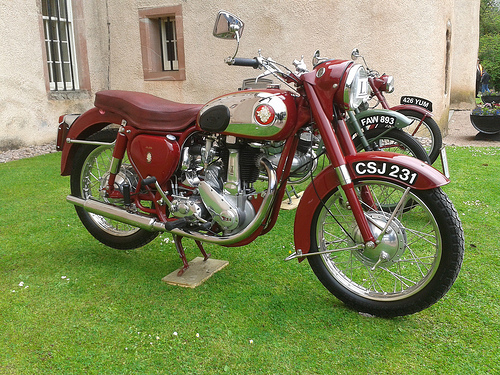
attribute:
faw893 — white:
[358, 103, 426, 154]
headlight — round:
[341, 65, 375, 112]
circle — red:
[248, 106, 315, 140]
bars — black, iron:
[155, 16, 173, 67]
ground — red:
[416, 117, 438, 141]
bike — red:
[63, 42, 465, 316]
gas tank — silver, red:
[194, 88, 309, 141]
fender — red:
[292, 133, 476, 285]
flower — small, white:
[170, 327, 187, 340]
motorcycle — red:
[45, 46, 495, 350]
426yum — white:
[400, 96, 430, 110]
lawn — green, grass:
[8, 240, 478, 370]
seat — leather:
[89, 81, 211, 135]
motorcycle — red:
[53, 20, 466, 322]